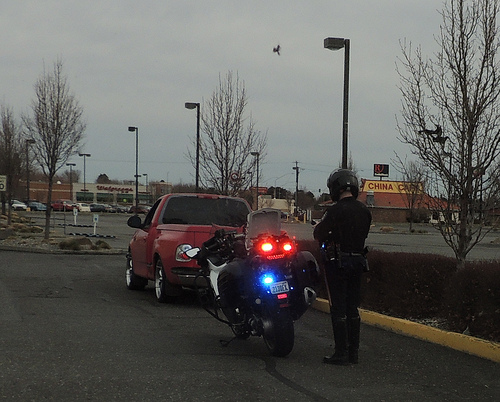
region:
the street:
[77, 304, 179, 367]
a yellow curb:
[430, 327, 448, 344]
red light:
[257, 240, 273, 253]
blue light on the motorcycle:
[255, 270, 271, 285]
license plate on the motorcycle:
[265, 281, 288, 292]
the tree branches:
[212, 76, 240, 136]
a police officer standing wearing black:
[317, 175, 380, 363]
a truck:
[135, 196, 198, 237]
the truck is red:
[158, 181, 228, 219]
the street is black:
[115, 342, 215, 389]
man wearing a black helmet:
[320, 168, 359, 200]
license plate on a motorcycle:
[260, 273, 293, 296]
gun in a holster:
[353, 242, 374, 272]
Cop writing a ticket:
[293, 164, 390, 364]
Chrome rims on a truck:
[118, 251, 136, 290]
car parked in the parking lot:
[38, 190, 140, 215]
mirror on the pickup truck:
[119, 209, 142, 231]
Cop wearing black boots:
[324, 311, 368, 368]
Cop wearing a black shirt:
[313, 191, 390, 284]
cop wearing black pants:
[319, 257, 366, 319]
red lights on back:
[257, 240, 299, 257]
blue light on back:
[254, 271, 276, 291]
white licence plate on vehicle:
[268, 278, 287, 290]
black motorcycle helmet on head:
[327, 161, 362, 188]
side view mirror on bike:
[182, 244, 203, 261]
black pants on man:
[323, 256, 375, 361]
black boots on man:
[321, 314, 360, 367]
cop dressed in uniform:
[308, 161, 382, 356]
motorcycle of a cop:
[190, 205, 310, 346]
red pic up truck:
[115, 180, 235, 305]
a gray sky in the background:
[9, 2, 418, 32]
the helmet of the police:
[326, 170, 359, 199]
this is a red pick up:
[126, 195, 252, 300]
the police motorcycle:
[200, 212, 317, 350]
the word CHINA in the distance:
[368, 182, 396, 192]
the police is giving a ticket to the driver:
[125, 167, 372, 369]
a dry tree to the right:
[396, 2, 495, 257]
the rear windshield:
[164, 193, 248, 224]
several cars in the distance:
[13, 199, 141, 213]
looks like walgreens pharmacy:
[96, 182, 139, 207]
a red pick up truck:
[95, 162, 248, 305]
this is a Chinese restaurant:
[332, 159, 454, 230]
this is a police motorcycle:
[185, 205, 332, 357]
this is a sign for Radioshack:
[366, 155, 398, 182]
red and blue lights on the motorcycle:
[244, 227, 306, 302]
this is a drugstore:
[70, 170, 150, 210]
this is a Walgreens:
[66, 170, 152, 212]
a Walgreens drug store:
[69, 175, 149, 207]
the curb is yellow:
[303, 283, 497, 376]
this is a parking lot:
[1, 173, 497, 400]